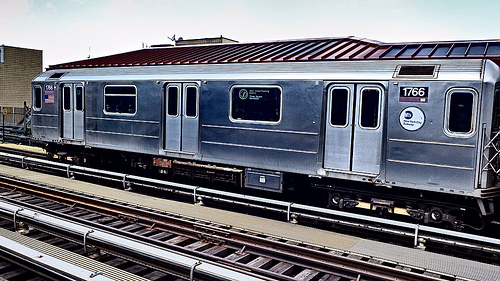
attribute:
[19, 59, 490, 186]
train — passenger 